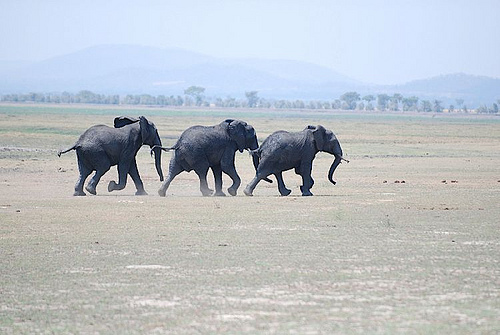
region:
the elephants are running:
[57, 107, 355, 209]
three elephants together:
[53, 102, 352, 204]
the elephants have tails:
[51, 136, 301, 167]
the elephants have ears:
[113, 111, 327, 156]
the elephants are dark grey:
[48, 110, 356, 202]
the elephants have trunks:
[143, 140, 355, 168]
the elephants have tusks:
[141, 139, 367, 173]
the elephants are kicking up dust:
[23, 166, 297, 210]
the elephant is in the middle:
[145, 112, 271, 202]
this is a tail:
[146, 138, 178, 157]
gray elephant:
[70, 117, 164, 196]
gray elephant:
[180, 117, 256, 186]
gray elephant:
[263, 121, 355, 189]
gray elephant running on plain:
[260, 124, 342, 198]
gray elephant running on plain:
[159, 117, 256, 197]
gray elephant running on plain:
[59, 119, 168, 200]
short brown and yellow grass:
[33, 210, 95, 243]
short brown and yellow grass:
[109, 237, 184, 268]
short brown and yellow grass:
[243, 227, 321, 274]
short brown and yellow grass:
[368, 201, 419, 276]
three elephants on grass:
[67, 100, 343, 228]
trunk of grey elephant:
[328, 158, 352, 190]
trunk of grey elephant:
[241, 150, 268, 185]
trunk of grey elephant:
[146, 151, 172, 186]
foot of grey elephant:
[131, 181, 149, 202]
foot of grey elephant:
[153, 179, 182, 201]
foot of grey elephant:
[197, 184, 213, 198]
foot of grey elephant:
[278, 183, 298, 198]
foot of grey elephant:
[227, 179, 240, 197]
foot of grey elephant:
[198, 175, 218, 195]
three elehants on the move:
[62, 107, 390, 197]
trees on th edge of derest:
[8, 91, 494, 108]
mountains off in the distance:
[11, 34, 499, 96]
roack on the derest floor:
[382, 171, 462, 191]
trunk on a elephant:
[323, 147, 351, 185]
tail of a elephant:
[147, 144, 169, 167]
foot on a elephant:
[105, 179, 121, 196]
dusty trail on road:
[33, 186, 485, 223]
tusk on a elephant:
[332, 154, 359, 166]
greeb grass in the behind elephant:
[8, 102, 187, 119]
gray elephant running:
[60, 115, 173, 203]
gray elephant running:
[164, 121, 256, 190]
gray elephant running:
[261, 119, 346, 199]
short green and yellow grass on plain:
[16, 246, 77, 273]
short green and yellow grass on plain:
[120, 232, 165, 262]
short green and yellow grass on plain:
[296, 242, 366, 287]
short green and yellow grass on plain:
[391, 187, 461, 233]